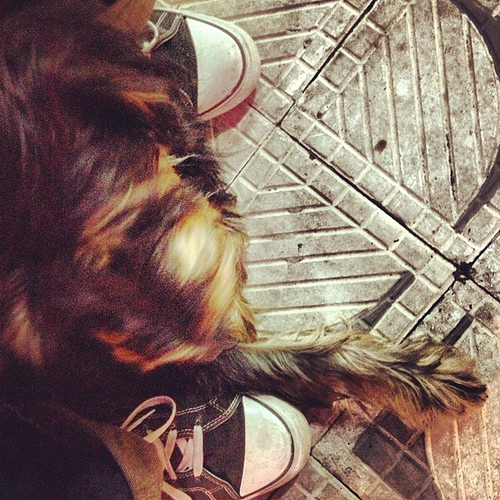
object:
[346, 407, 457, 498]
black tiles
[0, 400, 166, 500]
jeans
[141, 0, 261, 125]
shoe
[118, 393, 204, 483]
lace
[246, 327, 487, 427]
paw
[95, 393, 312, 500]
shoe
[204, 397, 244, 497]
section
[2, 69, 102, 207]
brown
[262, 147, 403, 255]
dirt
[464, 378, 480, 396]
toenail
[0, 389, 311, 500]
leg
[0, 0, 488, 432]
coat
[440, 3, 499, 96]
tile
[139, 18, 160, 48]
lace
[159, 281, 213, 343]
brown fur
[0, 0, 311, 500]
person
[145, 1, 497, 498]
floor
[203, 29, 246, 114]
toes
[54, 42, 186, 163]
ear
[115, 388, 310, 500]
feet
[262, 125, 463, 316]
ornate tile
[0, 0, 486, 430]
dog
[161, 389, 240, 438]
seams